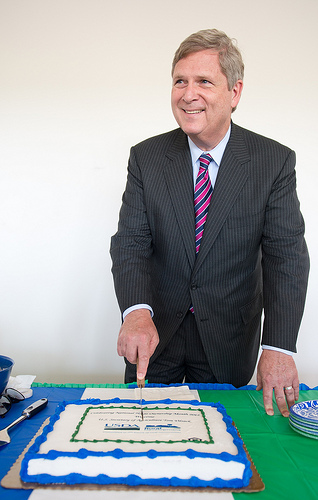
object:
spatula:
[0, 395, 49, 445]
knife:
[137, 352, 146, 421]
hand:
[116, 309, 160, 381]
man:
[110, 28, 309, 419]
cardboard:
[0, 412, 269, 493]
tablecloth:
[0, 383, 318, 500]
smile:
[178, 104, 208, 117]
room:
[0, 0, 318, 498]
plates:
[292, 399, 317, 420]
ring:
[285, 385, 292, 392]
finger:
[283, 383, 295, 407]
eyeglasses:
[0, 386, 25, 417]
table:
[0, 380, 318, 499]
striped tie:
[193, 151, 215, 258]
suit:
[111, 115, 309, 384]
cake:
[19, 397, 252, 488]